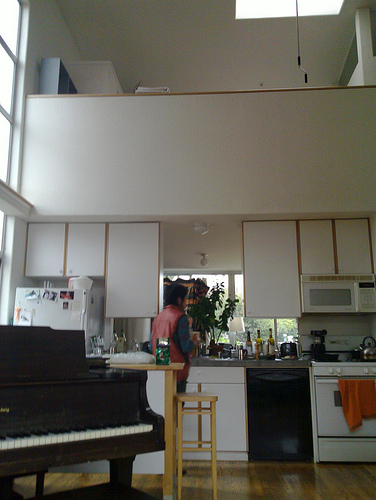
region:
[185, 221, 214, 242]
a light above a kitchen counter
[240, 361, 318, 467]
a black dishwasher in a kitchen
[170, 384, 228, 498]
a wooden bar stool in kitchen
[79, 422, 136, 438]
the white keys on a piano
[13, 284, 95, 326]
the top door of a white fridge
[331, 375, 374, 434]
an orange towel on a stove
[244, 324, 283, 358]
bottles near a kitchen window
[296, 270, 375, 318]
a microwave oven above a stove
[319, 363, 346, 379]
the white knobs on a stove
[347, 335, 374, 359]
a silver tea kettle on a stove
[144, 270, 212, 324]
face of the person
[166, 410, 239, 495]
a table on ground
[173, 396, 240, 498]
a table on floor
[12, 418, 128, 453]
a part of swiches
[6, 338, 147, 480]
a pianio set near wall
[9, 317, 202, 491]
a pianio set on the floor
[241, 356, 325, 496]
a door in the room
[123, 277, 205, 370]
a man waring jacket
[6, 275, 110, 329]
a fridge near wall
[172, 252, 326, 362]
a window in the room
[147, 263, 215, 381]
person in the kitchen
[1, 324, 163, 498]
Black piano with white keyes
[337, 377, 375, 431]
Bright orange dish towel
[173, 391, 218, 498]
Tall light colored wood stool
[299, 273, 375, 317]
White top mounted microwave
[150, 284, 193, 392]
Person standing wearing a red vest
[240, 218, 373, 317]
White kitchen cupboards with light wood trim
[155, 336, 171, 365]
Small green package of chocolates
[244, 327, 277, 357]
Three glass condiment bottles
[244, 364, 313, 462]
Black automatic dish washer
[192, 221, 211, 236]
White ceiling mounted light fixture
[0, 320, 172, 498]
piano in a room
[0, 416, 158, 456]
keys on a piano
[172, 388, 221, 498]
stool next to a counter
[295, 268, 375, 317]
microwave oven in a kitchen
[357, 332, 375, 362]
tea pot on a stove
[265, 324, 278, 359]
bottle on a kitchen counter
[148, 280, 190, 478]
person standing in a kitchen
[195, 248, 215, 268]
light on a ceiling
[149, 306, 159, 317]
knob on a cabinet door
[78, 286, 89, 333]
handle on a refrigerator